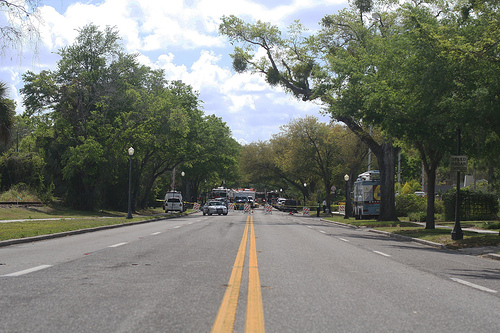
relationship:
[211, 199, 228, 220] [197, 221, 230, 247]
police car in street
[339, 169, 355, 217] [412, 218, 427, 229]
lamp post near sidewalk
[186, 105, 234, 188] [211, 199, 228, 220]
trees near police car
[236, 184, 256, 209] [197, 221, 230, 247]
emergency vehicle blocking street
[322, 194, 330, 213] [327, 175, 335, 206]
man near tree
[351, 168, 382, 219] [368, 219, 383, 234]
truck on grass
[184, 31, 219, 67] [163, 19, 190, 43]
sky has clouds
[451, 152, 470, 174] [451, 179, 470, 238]
sign on pole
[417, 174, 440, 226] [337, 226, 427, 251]
tree has shadow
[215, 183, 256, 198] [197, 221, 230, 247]
fire truck on street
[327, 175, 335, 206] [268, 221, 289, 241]
tree next to road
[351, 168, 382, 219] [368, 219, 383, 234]
news van on grass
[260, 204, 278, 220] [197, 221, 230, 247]
barricade in street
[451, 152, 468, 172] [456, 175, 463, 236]
sign on post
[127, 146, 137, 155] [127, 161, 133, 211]
light on post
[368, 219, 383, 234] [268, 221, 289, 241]
grass near road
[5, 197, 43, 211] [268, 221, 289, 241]
train track near road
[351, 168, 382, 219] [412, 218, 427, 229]
bus on sidewalk